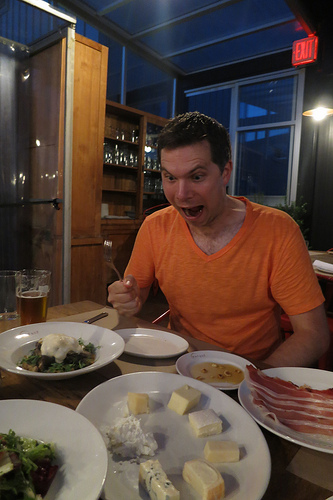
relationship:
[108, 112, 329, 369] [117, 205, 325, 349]
man in shirt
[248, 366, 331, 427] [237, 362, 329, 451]
bacon on plate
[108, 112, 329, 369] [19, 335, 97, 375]
man looks at salad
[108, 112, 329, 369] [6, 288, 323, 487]
man looks at table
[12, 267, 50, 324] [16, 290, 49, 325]
glass containing beer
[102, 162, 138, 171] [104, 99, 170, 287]
shelf mounted into cabinet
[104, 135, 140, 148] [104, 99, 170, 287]
shelf mounted into cabinet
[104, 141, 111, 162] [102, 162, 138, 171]
glass sitting on top of shelf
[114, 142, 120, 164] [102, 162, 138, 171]
glass sitting on top of shelf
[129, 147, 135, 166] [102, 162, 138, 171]
glass sitting on top of shelf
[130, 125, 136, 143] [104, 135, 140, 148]
glass sitting on top of shelf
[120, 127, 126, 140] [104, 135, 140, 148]
glass sitting on top of shelf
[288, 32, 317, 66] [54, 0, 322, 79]
exit sign hanging from ceiling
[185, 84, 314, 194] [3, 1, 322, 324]
window in building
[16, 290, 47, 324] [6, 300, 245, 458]
beer on table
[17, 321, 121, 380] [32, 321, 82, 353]
salad with dressing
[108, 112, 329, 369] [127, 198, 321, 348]
man in shirt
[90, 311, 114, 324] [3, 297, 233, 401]
utensil on table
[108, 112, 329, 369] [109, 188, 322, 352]
man wearing shirt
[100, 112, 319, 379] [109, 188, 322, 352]
man wearing shirt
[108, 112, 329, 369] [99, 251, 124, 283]
man holding fork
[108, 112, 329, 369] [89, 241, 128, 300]
man holding fork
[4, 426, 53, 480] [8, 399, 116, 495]
salad in a bowl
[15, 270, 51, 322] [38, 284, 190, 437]
beer on table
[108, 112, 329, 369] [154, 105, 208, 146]
man has hair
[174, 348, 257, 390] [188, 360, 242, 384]
plate has sauce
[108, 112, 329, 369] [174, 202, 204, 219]
man has mouth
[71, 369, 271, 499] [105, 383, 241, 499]
plate has cheese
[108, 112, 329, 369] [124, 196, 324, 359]
man has shirt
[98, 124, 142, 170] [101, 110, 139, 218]
glasses on shelves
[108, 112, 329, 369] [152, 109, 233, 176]
man has hair